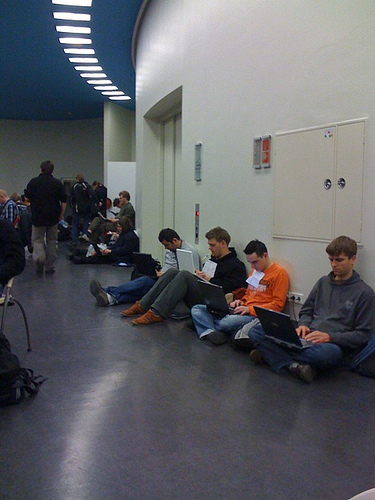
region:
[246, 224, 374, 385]
a male is wearing gray hoodie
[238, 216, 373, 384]
a person sitting down with his laptop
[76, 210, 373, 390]
a group of people sitting down with their laptops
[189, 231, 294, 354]
this person wearing orange shirt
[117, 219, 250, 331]
this person is wearing black hoodie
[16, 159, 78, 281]
this person is wearing a black shirt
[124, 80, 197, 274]
a closed elevator door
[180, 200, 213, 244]
buttons for an elevator door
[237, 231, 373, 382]
this person is crossing his legs while sitting down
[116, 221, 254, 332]
this person is wearing a brown dress shoe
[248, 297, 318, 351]
Laptop computer on a lap.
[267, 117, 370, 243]
Door on the wall.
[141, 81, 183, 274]
Elevator in the background.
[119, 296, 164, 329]
Orange shoes on the feet.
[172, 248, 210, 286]
white laptop computer on a lap.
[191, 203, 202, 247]
Elevator buttons on the wall.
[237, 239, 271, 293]
man holding paper under his chin.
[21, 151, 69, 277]
Man walking in the background.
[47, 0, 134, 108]
Ceiling lights in the ceiling.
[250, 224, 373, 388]
Man sitting on the floor.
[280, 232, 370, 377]
man wearing gray jacket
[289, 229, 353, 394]
man wearning blue jeans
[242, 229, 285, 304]
man wearing orange shirt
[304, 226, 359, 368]
man looking at lap top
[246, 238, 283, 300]
man wearing blue jeans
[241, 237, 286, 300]
man looking at lap top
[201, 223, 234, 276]
man wearing black jacket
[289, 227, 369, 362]
man sitting on floor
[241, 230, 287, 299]
man sitting on floor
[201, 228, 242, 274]
man sitting on floor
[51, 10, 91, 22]
a ceiling light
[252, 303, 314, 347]
a gray laptop computer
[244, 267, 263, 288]
a piece of paper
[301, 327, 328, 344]
the hand of a man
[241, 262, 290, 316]
a man's orange shirt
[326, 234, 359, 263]
a man's short cut brown hair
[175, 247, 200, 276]
a white laptop computer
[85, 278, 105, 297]
the shoe of a man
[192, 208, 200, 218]
an elevator button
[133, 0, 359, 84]
part of a white painted wall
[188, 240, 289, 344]
a man in an orange shirt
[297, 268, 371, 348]
a gray shirt on a man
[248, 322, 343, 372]
blue jeans on a man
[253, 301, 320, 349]
a laptop on a man's lap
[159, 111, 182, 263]
elevator doors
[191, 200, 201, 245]
an elevator control panel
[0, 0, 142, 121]
a blue ceiling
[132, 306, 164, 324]
a brown shoe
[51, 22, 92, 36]
a light in the ceiling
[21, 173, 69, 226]
a black shirt on a man